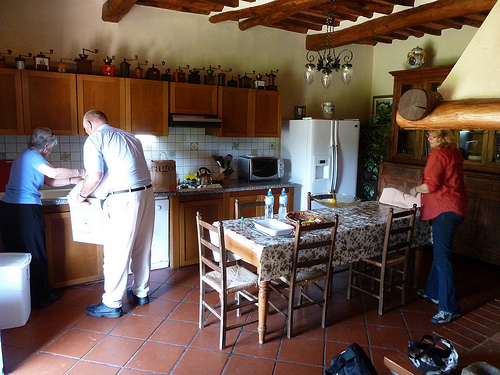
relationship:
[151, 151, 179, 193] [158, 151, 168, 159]
bag has a handle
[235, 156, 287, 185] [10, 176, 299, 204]
oven on counter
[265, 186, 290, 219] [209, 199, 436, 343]
bottles are on table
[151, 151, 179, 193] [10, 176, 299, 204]
bag on counter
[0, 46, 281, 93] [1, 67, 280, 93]
coffee grinders are on shelf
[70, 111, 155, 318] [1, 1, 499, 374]
person in kitchen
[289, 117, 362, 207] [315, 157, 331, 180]
refrigerator has an icemaker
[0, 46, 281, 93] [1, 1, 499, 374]
coffee grinders are in kitchen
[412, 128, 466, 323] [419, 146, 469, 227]
woman wearing a shirt